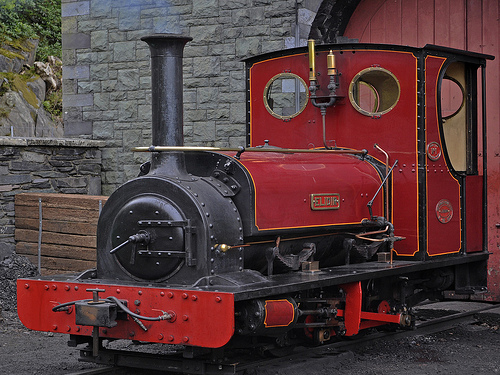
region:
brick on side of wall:
[120, 72, 140, 93]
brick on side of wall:
[229, 100, 242, 123]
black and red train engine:
[59, 29, 494, 367]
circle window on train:
[354, 70, 394, 117]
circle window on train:
[264, 72, 307, 127]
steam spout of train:
[145, 6, 181, 159]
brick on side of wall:
[195, 2, 216, 20]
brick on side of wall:
[53, 33, 84, 50]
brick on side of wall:
[91, 119, 109, 140]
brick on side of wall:
[40, 146, 67, 164]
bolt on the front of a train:
[210, 294, 223, 306]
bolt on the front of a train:
[187, 290, 196, 303]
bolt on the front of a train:
[178, 288, 188, 301]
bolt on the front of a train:
[177, 311, 191, 323]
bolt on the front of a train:
[180, 332, 189, 344]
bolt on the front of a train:
[165, 330, 176, 344]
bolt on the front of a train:
[155, 330, 167, 342]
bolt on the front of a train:
[164, 290, 174, 300]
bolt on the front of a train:
[62, 282, 71, 294]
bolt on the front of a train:
[22, 280, 30, 291]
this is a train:
[129, 98, 491, 353]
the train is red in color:
[326, 76, 419, 180]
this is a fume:
[135, 8, 179, 28]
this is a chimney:
[153, 40, 196, 125]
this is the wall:
[63, 39, 125, 116]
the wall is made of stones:
[76, 50, 133, 109]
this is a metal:
[437, 303, 475, 343]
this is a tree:
[8, 6, 53, 36]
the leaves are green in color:
[0, 6, 44, 25]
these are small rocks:
[396, 340, 438, 371]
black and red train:
[20, 35, 494, 357]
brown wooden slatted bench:
[13, 194, 108, 269]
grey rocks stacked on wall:
[2, 139, 101, 308]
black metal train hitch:
[66, 290, 128, 352]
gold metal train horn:
[306, 37, 335, 82]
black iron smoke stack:
[141, 32, 192, 153]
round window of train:
[263, 71, 306, 121]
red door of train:
[424, 57, 484, 257]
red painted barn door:
[343, 3, 498, 299]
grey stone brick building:
[59, 3, 334, 198]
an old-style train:
[12, 19, 490, 344]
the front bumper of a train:
[15, 270, 250, 351]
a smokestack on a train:
[127, 22, 225, 177]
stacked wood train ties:
[7, 181, 127, 291]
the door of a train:
[415, 44, 494, 259]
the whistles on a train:
[294, 27, 351, 123]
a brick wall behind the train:
[85, 14, 277, 139]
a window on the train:
[257, 72, 315, 132]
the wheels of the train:
[250, 285, 433, 336]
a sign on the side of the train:
[302, 185, 348, 219]